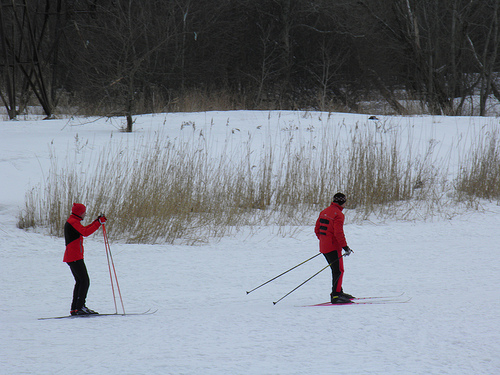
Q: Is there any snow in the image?
A: Yes, there is snow.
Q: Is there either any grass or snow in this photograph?
A: Yes, there is snow.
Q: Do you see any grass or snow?
A: Yes, there is snow.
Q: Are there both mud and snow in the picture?
A: No, there is snow but no mud.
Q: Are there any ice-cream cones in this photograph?
A: No, there are no ice-cream cones.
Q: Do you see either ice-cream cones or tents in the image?
A: No, there are no ice-cream cones or tents.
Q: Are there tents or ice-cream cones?
A: No, there are no ice-cream cones or tents.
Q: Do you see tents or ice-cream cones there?
A: No, there are no ice-cream cones or tents.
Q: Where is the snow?
A: The snow is on the ground.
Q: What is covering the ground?
A: The snow is covering the ground.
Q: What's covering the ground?
A: The snow is covering the ground.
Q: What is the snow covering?
A: The snow is covering the ground.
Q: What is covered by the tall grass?
A: The snow is covered by the grass.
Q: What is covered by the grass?
A: The snow is covered by the grass.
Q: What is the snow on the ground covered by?
A: The snow is covered by the grass.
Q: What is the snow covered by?
A: The snow is covered by the grass.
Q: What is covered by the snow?
A: The ground is covered by the snow.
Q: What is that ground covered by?
A: The ground is covered by the snow.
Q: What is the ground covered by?
A: The ground is covered by the snow.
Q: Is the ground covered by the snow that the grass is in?
A: Yes, the ground is covered by the snow.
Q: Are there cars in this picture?
A: No, there are no cars.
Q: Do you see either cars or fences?
A: No, there are no cars or fences.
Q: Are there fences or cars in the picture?
A: No, there are no cars or fences.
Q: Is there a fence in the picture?
A: No, there are no fences.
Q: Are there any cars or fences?
A: No, there are no fences or cars.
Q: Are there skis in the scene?
A: Yes, there are skis.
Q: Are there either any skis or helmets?
A: Yes, there are skis.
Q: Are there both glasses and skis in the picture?
A: No, there are skis but no glasses.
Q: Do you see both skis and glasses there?
A: No, there are skis but no glasses.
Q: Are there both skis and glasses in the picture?
A: No, there are skis but no glasses.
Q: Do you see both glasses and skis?
A: No, there are skis but no glasses.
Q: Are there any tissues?
A: No, there are no tissues.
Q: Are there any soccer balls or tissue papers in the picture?
A: No, there are no tissue papers or soccer balls.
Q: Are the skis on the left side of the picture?
A: Yes, the skis are on the left of the image.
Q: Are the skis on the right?
A: No, the skis are on the left of the image.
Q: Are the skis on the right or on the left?
A: The skis are on the left of the image.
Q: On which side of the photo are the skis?
A: The skis are on the left of the image.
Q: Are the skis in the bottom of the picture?
A: Yes, the skis are in the bottom of the image.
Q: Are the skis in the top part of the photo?
A: No, the skis are in the bottom of the image.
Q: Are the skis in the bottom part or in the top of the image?
A: The skis are in the bottom of the image.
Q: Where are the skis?
A: The skis are on the snow.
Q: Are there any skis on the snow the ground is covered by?
A: Yes, there are skis on the snow.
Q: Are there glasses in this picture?
A: No, there are no glasses.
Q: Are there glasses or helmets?
A: No, there are no glasses or helmets.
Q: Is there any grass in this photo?
A: Yes, there is grass.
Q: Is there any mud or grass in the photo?
A: Yes, there is grass.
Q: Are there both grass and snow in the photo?
A: Yes, there are both grass and snow.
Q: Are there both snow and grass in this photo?
A: Yes, there are both grass and snow.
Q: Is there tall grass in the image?
A: Yes, there is tall grass.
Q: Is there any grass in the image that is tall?
A: Yes, there is tall grass.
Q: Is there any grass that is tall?
A: Yes, there is grass that is tall.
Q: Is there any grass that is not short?
A: Yes, there is tall grass.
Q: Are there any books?
A: No, there are no books.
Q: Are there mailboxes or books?
A: No, there are no books or mailboxes.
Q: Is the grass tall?
A: Yes, the grass is tall.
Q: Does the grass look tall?
A: Yes, the grass is tall.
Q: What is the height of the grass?
A: The grass is tall.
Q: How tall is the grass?
A: The grass is tall.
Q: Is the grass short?
A: No, the grass is tall.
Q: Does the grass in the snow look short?
A: No, the grass is tall.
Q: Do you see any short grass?
A: No, there is grass but it is tall.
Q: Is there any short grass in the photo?
A: No, there is grass but it is tall.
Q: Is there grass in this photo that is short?
A: No, there is grass but it is tall.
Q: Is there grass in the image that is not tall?
A: No, there is grass but it is tall.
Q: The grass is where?
A: The grass is in the snow.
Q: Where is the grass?
A: The grass is in the snow.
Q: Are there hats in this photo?
A: Yes, there is a hat.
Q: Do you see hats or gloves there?
A: Yes, there is a hat.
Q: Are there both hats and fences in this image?
A: No, there is a hat but no fences.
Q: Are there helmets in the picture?
A: No, there are no helmets.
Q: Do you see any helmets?
A: No, there are no helmets.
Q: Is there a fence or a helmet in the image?
A: No, there are no helmets or fences.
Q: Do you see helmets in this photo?
A: No, there are no helmets.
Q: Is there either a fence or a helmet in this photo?
A: No, there are no helmets or fences.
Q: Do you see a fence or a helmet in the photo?
A: No, there are no helmets or fences.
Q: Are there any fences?
A: No, there are no fences.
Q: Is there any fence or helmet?
A: No, there are no fences or helmets.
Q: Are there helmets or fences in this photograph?
A: No, there are no fences or helmets.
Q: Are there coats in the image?
A: Yes, there is a coat.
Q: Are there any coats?
A: Yes, there is a coat.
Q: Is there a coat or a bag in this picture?
A: Yes, there is a coat.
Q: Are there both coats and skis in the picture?
A: Yes, there are both a coat and skis.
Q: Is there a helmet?
A: No, there are no helmets.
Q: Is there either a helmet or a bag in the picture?
A: No, there are no helmets or bags.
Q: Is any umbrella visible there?
A: No, there are no umbrellas.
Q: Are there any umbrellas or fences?
A: No, there are no umbrellas or fences.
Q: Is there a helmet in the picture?
A: No, there are no helmets.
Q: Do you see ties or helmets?
A: No, there are no helmets or ties.